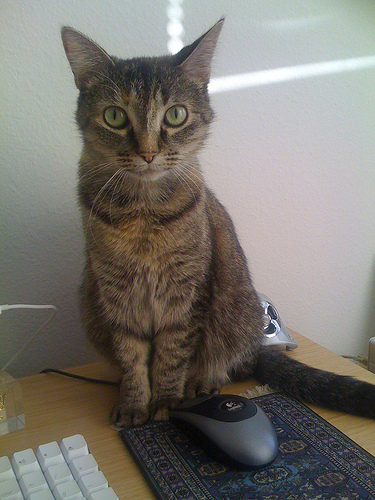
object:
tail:
[256, 345, 374, 420]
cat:
[60, 18, 375, 431]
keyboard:
[0, 432, 121, 500]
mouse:
[168, 393, 278, 470]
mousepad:
[118, 391, 374, 500]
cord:
[38, 368, 121, 386]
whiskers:
[73, 160, 213, 243]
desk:
[0, 326, 375, 499]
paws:
[113, 397, 173, 430]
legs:
[113, 326, 200, 402]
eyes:
[104, 105, 188, 129]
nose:
[137, 136, 159, 163]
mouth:
[128, 168, 172, 180]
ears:
[59, 16, 227, 92]